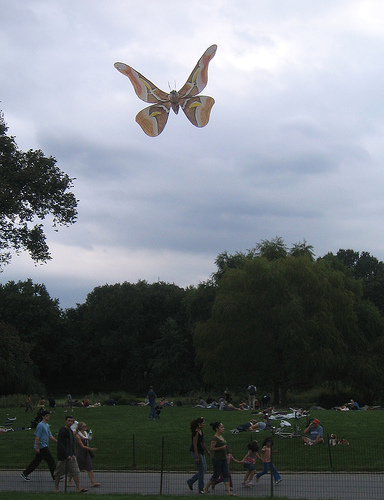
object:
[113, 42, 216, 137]
kite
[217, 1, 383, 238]
sky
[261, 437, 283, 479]
girls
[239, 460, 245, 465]
hands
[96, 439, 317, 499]
fence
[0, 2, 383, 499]
park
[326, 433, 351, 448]
dog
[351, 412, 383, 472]
grass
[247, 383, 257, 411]
people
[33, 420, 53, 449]
shirt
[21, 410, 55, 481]
man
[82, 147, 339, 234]
clouds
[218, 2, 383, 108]
sun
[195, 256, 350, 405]
shady trees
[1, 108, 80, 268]
tree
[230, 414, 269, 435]
people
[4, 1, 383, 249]
flight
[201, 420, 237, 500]
people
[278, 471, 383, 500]
park path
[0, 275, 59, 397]
trees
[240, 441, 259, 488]
kids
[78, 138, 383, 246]
sky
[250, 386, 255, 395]
backpack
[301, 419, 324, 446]
man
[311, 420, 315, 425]
cellphone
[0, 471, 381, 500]
walkway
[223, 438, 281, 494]
children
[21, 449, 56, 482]
pants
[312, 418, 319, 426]
hat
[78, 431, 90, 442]
ring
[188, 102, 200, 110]
yellow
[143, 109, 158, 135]
white color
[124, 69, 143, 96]
orange color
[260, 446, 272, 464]
shirts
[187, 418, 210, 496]
two women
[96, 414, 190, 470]
grass